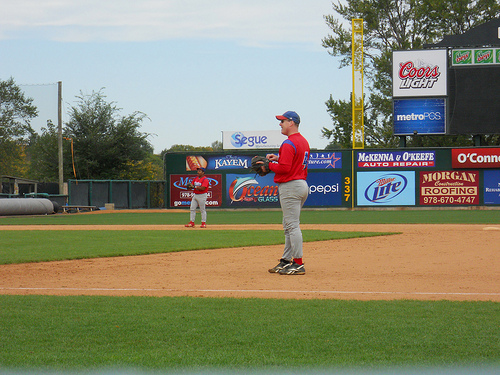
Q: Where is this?
A: This is at the field.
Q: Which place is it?
A: It is a field.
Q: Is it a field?
A: Yes, it is a field.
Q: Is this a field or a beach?
A: It is a field.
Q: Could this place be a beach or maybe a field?
A: It is a field.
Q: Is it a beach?
A: No, it is a field.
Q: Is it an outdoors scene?
A: Yes, it is outdoors.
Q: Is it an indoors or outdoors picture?
A: It is outdoors.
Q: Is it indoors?
A: No, it is outdoors.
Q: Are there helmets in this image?
A: No, there are no helmets.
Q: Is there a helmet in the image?
A: No, there are no helmets.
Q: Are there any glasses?
A: No, there are no glasses.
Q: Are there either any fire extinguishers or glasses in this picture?
A: No, there are no glasses or fire extinguishers.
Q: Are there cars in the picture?
A: No, there are no cars.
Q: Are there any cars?
A: No, there are no cars.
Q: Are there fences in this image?
A: Yes, there is a fence.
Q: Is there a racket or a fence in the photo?
A: Yes, there is a fence.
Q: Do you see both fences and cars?
A: No, there is a fence but no cars.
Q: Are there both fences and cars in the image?
A: No, there is a fence but no cars.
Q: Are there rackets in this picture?
A: No, there are no rackets.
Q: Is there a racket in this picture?
A: No, there are no rackets.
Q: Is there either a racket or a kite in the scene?
A: No, there are no rackets or kites.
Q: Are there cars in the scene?
A: No, there are no cars.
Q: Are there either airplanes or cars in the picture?
A: No, there are no cars or airplanes.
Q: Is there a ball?
A: No, there are no balls.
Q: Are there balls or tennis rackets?
A: No, there are no balls or tennis rackets.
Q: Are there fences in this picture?
A: Yes, there is a fence.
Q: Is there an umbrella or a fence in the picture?
A: Yes, there is a fence.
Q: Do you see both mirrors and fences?
A: No, there is a fence but no mirrors.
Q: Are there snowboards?
A: No, there are no snowboards.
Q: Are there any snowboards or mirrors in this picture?
A: No, there are no snowboards or mirrors.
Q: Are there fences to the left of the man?
A: Yes, there is a fence to the left of the man.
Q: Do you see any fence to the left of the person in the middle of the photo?
A: Yes, there is a fence to the left of the man.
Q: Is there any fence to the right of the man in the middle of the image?
A: No, the fence is to the left of the man.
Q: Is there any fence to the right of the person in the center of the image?
A: No, the fence is to the left of the man.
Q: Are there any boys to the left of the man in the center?
A: No, there is a fence to the left of the man.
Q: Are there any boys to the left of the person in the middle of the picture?
A: No, there is a fence to the left of the man.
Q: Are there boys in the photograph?
A: No, there are no boys.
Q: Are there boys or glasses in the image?
A: No, there are no boys or glasses.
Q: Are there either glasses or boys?
A: No, there are no boys or glasses.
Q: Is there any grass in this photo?
A: Yes, there is grass.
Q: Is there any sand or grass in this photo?
A: Yes, there is grass.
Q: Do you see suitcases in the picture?
A: No, there are no suitcases.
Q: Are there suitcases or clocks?
A: No, there are no suitcases or clocks.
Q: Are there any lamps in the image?
A: No, there are no lamps.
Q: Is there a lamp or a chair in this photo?
A: No, there are no lamps or chairs.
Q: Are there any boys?
A: No, there are no boys.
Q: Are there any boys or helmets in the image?
A: No, there are no boys or helmets.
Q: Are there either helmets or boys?
A: No, there are no boys or helmets.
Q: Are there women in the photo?
A: No, there are no women.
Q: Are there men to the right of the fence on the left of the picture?
A: Yes, there is a man to the right of the fence.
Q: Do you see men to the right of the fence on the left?
A: Yes, there is a man to the right of the fence.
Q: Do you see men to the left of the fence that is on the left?
A: No, the man is to the right of the fence.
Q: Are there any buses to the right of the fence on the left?
A: No, there is a man to the right of the fence.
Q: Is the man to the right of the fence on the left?
A: Yes, the man is to the right of the fence.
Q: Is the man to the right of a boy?
A: No, the man is to the right of the fence.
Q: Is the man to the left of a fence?
A: No, the man is to the right of a fence.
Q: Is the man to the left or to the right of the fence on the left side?
A: The man is to the right of the fence.